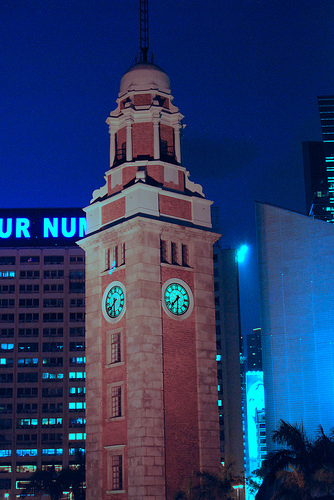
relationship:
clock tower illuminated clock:
[164, 276, 190, 318] [164, 276, 190, 318]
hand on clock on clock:
[164, 293, 184, 310] [169, 290, 190, 309]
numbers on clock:
[179, 288, 186, 315] [169, 290, 190, 309]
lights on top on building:
[0, 201, 95, 248] [3, 215, 122, 498]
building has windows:
[0, 206, 92, 497] [0, 251, 84, 498]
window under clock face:
[111, 329, 123, 363] [100, 280, 126, 323]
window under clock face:
[105, 383, 119, 417] [100, 280, 126, 323]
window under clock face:
[109, 453, 123, 493] [100, 280, 126, 323]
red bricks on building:
[159, 323, 199, 499] [81, 64, 219, 497]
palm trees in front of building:
[246, 414, 325, 487] [81, 64, 219, 497]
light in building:
[1, 269, 16, 277] [2, 206, 84, 499]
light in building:
[0, 342, 11, 349] [2, 206, 84, 499]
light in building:
[19, 419, 64, 423] [2, 206, 84, 499]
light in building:
[42, 371, 64, 381] [2, 206, 84, 499]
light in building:
[66, 431, 86, 441] [2, 206, 84, 499]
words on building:
[4, 203, 100, 239] [0, 207, 241, 493]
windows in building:
[1, 272, 16, 278] [0, 207, 241, 493]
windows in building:
[39, 312, 62, 324] [0, 207, 241, 493]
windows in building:
[41, 371, 62, 380] [0, 207, 241, 493]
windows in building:
[16, 388, 37, 400] [0, 207, 241, 493]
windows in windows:
[16, 388, 37, 400] [44, 269, 62, 277]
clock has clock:
[164, 276, 190, 318] [164, 276, 190, 318]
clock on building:
[169, 290, 190, 309] [81, 64, 219, 497]